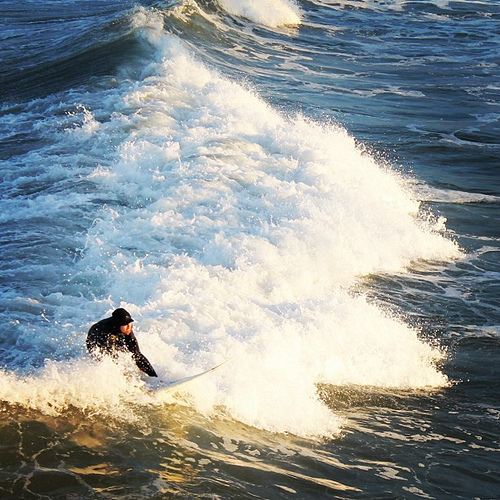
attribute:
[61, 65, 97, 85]
giraffe — standing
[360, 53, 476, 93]
water — rough, white, wet, splashing, vicious, rugged, tempestousoy, fervent, tumultuous, boisterous, dark, turbulent, blue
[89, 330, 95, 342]
wetsuit — black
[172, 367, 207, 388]
surfboard — white, whitey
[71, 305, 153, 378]
surfer — bending, riding, surfing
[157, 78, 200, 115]
wave — crashing, cresting, small, large, breaking, white, splashing, churning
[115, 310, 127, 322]
cap — black